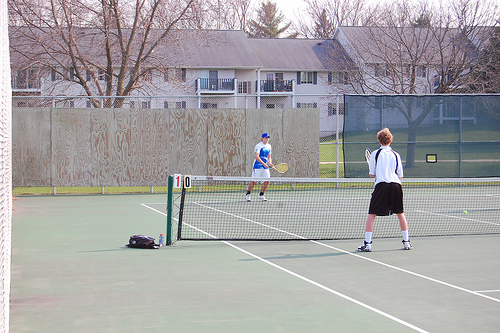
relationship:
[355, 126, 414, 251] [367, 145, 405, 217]
man wearing black and white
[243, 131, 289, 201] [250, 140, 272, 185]
man wearing blue and white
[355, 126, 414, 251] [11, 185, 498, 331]
man playing on court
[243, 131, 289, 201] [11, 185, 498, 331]
man playing on court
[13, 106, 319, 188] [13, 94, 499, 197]
boards attached to fence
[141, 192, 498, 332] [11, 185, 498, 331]
lines on top of court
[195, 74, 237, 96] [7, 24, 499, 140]
balcony on back of building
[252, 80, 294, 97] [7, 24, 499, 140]
balcony on back of building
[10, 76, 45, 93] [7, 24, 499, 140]
balcony on back of building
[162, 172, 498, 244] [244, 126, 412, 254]
net between tennis players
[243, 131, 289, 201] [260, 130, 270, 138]
man wearing hat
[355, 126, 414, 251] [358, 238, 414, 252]
man wearing shoes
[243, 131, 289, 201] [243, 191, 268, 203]
man wearing shoes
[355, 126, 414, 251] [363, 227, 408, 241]
man wearing socks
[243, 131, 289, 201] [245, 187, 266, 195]
man wearing socks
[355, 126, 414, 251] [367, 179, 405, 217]
man wearing shorts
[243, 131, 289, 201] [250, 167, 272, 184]
man wearing shorts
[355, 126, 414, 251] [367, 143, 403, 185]
man wearing shirt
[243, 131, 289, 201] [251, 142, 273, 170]
man wearing shirt